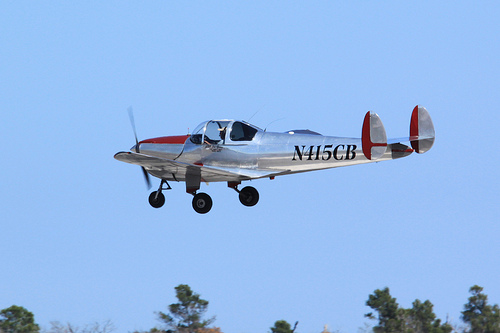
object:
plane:
[111, 103, 437, 215]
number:
[303, 142, 315, 164]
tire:
[186, 189, 217, 215]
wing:
[105, 145, 212, 173]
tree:
[391, 290, 449, 330]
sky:
[187, 17, 259, 51]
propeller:
[121, 104, 153, 193]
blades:
[122, 104, 145, 151]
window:
[195, 114, 257, 148]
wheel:
[221, 184, 297, 213]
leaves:
[385, 289, 428, 331]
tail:
[359, 109, 390, 160]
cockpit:
[182, 118, 278, 153]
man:
[200, 123, 226, 146]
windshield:
[229, 115, 258, 149]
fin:
[406, 104, 437, 155]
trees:
[151, 282, 219, 320]